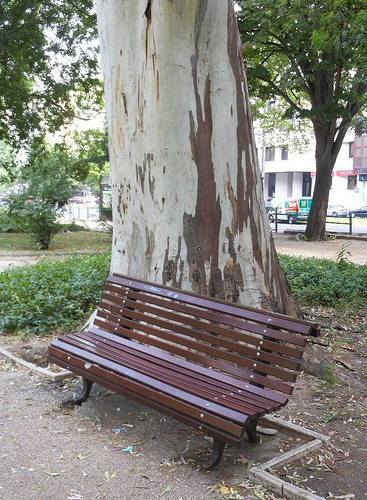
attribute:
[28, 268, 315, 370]
bench — one ., visible.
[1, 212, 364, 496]
ground — trim .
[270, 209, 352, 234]
fence — background.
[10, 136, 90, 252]
bush — tall, green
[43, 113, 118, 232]
building — tall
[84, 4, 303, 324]
tree — missing bark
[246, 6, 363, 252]
tree — missing bark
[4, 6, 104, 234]
tree — missing bark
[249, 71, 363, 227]
building — white, row.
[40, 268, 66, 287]
leaves — green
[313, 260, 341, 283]
leaves — green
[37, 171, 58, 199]
leaves — green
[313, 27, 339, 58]
leaves — green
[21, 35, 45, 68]
leaves — green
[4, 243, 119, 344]
grass — green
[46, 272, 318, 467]
bench — shiny, brown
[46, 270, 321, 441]
bench — missing.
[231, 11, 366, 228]
tree — brown, white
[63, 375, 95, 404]
black metal — metallic, bar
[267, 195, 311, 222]
van — red, white, blue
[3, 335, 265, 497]
walkway — side 